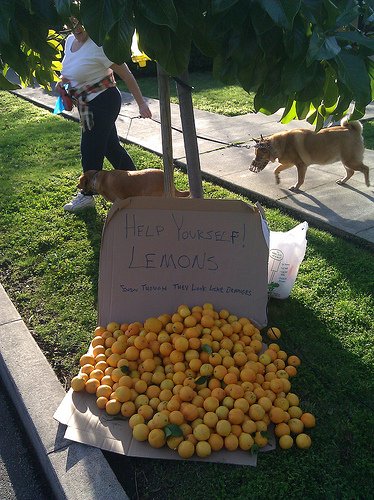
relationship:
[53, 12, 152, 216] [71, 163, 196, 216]
woman walking dog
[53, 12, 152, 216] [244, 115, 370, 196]
woman walking dog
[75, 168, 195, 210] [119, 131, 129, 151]
dog on leash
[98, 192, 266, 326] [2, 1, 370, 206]
box propped on tree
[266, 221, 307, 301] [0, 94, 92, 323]
plastic bag on grass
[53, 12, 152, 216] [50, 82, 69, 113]
woman carrying bag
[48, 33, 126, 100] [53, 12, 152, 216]
shirt wearing woman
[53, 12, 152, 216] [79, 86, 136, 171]
woman wearing pants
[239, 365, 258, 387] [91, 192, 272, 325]
lemon on cardboard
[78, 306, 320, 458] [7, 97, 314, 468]
lemons on ground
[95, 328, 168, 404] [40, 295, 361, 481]
lemons on ground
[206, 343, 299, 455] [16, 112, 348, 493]
lemons on ground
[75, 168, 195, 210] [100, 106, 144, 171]
dog on leash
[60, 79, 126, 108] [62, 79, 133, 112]
shirt around waist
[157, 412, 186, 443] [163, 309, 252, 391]
leaves on lemon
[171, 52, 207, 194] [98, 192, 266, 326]
pole behind box